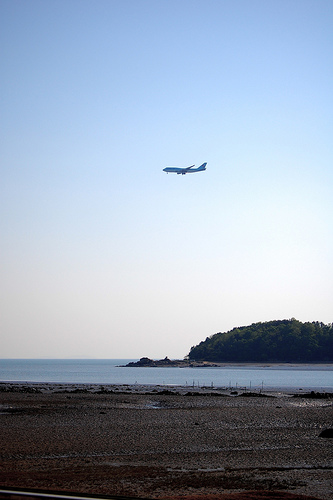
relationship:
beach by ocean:
[3, 382, 331, 494] [1, 357, 124, 387]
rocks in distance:
[116, 353, 225, 368] [29, 309, 322, 364]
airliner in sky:
[162, 162, 208, 175] [1, 1, 330, 361]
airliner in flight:
[161, 164, 210, 175] [130, 141, 294, 225]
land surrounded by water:
[114, 355, 221, 368] [1, 358, 328, 387]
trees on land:
[185, 321, 331, 362] [122, 354, 331, 368]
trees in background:
[185, 321, 331, 362] [90, 312, 327, 397]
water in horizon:
[1, 358, 328, 387] [0, 357, 186, 363]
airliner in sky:
[162, 162, 208, 175] [107, 88, 321, 129]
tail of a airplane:
[195, 159, 207, 172] [160, 160, 208, 177]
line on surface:
[3, 482, 84, 498] [1, 481, 99, 498]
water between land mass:
[263, 365, 328, 387] [190, 319, 331, 365]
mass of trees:
[178, 306, 329, 399] [225, 318, 281, 366]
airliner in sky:
[162, 162, 208, 175] [2, 0, 305, 313]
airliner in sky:
[162, 162, 208, 175] [18, 15, 320, 142]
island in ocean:
[115, 351, 218, 370] [1, 357, 331, 387]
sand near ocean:
[1, 379, 86, 394] [1, 357, 331, 387]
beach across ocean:
[128, 355, 319, 369] [3, 363, 331, 382]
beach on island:
[3, 382, 331, 494] [116, 357, 215, 368]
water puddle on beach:
[137, 395, 169, 408] [3, 382, 331, 494]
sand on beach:
[1, 379, 279, 394] [54, 331, 210, 405]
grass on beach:
[0, 379, 319, 402] [54, 331, 210, 405]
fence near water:
[166, 377, 264, 387] [31, 369, 237, 378]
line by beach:
[3, 482, 84, 498] [12, 389, 301, 465]